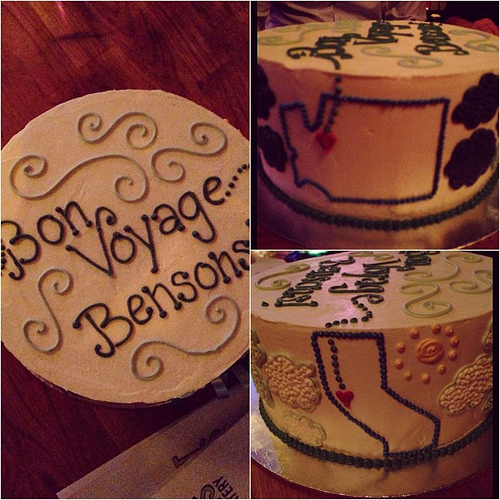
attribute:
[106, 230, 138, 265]
letter — black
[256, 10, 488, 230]
cake — top 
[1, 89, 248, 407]
cake — going away 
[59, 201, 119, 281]
letter — black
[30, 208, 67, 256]
letter — black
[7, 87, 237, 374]
cake — frosted, decorative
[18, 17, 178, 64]
table — wooden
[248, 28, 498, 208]
cake — decorated , side shot 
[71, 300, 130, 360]
letter — black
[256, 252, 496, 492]
cake — bakery baked, top , decorated 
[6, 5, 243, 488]
table — wooden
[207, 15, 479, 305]
cake — three photographs , one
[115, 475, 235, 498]
menus — couple 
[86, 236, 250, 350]
bensons — Bon Voyage